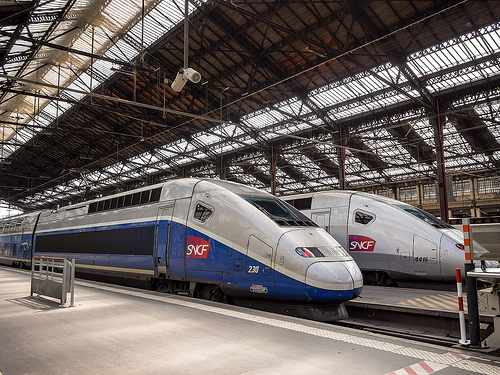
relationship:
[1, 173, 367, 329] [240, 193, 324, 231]
train has windshield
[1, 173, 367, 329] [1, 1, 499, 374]
train inside of station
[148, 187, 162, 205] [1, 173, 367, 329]
window on side of train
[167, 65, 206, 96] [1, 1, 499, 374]
light inside of station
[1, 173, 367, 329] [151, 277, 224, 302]
train has wheel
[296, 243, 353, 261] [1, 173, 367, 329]
light on front of train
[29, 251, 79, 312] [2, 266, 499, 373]
equipment on top of platform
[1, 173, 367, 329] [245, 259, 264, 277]
train has numbers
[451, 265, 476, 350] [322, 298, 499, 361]
marker on side of track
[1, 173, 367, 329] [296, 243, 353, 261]
train has light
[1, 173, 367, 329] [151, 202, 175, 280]
train has door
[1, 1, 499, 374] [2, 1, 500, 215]
station has roof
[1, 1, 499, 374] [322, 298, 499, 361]
station has track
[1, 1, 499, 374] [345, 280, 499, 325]
station has ramp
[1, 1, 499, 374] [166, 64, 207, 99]
station has loudspeakers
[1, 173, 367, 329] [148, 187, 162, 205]
train has window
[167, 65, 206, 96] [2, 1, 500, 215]
light hanging from roof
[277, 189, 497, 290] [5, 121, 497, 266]
train in background